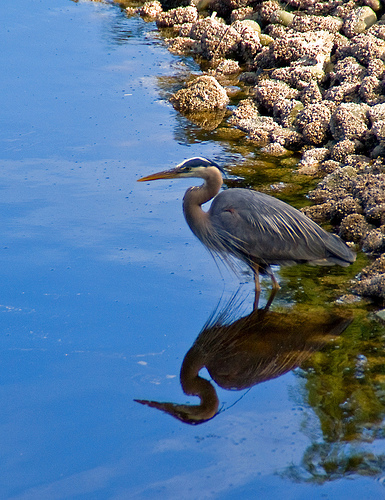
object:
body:
[209, 187, 356, 265]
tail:
[324, 233, 356, 267]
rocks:
[238, 18, 261, 34]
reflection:
[131, 292, 349, 427]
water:
[0, 5, 383, 500]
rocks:
[345, 6, 377, 39]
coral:
[256, 141, 296, 157]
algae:
[245, 161, 296, 182]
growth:
[157, 70, 238, 119]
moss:
[306, 350, 375, 441]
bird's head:
[132, 398, 217, 432]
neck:
[179, 353, 220, 410]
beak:
[136, 166, 182, 182]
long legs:
[251, 264, 261, 312]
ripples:
[100, 23, 165, 48]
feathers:
[217, 232, 251, 258]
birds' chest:
[180, 204, 206, 249]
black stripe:
[175, 156, 212, 168]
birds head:
[136, 156, 219, 180]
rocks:
[273, 4, 302, 31]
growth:
[168, 74, 230, 109]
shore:
[117, 0, 385, 349]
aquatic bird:
[136, 156, 357, 311]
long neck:
[181, 172, 224, 240]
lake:
[5, 2, 378, 496]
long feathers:
[217, 193, 326, 245]